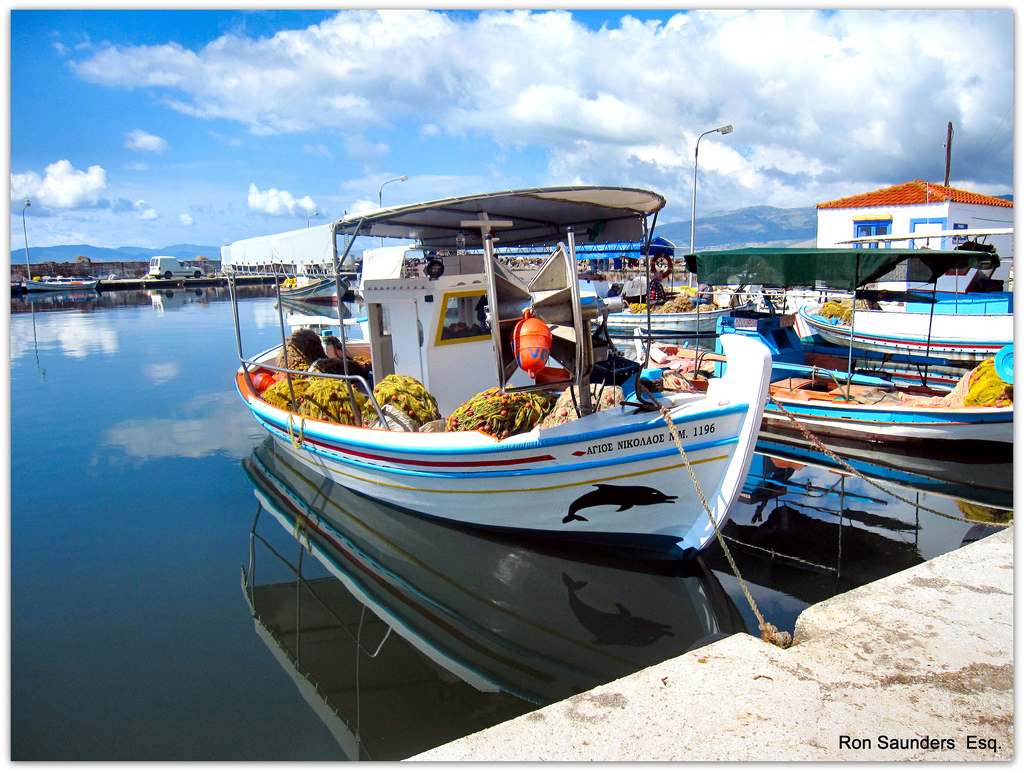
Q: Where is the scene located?
A: Ocean.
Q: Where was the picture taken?
A: At a dock.